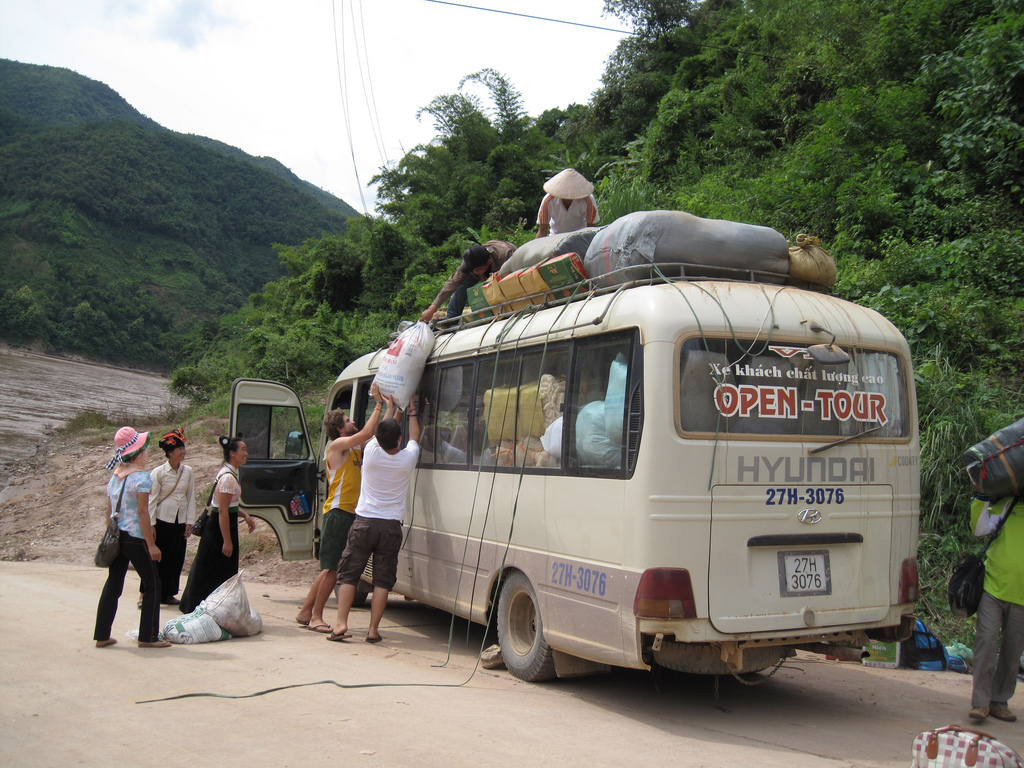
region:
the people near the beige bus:
[89, 168, 1022, 729]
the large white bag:
[367, 319, 432, 411]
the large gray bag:
[585, 208, 789, 289]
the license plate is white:
[784, 553, 826, 593]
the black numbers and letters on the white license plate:
[781, 552, 830, 594]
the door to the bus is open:
[222, 260, 919, 685]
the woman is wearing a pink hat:
[93, 429, 170, 651]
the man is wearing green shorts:
[298, 380, 379, 627]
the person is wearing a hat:
[532, 165, 597, 235]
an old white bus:
[210, 214, 941, 699]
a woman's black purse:
[93, 477, 139, 573]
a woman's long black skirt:
[168, 505, 260, 619]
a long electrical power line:
[427, 2, 642, 45]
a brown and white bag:
[908, 723, 1011, 766]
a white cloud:
[118, 31, 293, 137]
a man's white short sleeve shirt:
[354, 442, 424, 519]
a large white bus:
[324, 342, 890, 678]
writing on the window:
[695, 341, 899, 444]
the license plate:
[778, 556, 832, 594]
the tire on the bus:
[483, 575, 554, 684]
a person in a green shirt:
[957, 437, 1021, 731]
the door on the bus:
[233, 380, 319, 564]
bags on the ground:
[163, 574, 285, 644]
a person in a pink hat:
[95, 424, 162, 625]